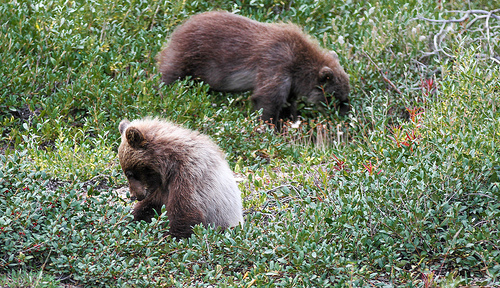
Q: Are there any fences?
A: No, there are no fences.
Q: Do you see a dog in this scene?
A: No, there are no dogs.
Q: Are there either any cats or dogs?
A: No, there are no dogs or cats.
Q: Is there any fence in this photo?
A: No, there are no fences.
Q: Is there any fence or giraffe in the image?
A: No, there are no fences or giraffes.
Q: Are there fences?
A: No, there are no fences.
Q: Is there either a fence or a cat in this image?
A: No, there are no fences or cats.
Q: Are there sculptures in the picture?
A: No, there are no sculptures.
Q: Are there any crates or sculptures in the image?
A: No, there are no sculptures or crates.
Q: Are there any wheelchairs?
A: No, there are no wheelchairs.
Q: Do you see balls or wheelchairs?
A: No, there are no wheelchairs or balls.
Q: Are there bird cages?
A: No, there are no bird cages.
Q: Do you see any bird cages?
A: No, there are no bird cages.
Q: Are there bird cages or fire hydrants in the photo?
A: No, there are no bird cages or fire hydrants.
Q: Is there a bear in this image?
A: Yes, there is a bear.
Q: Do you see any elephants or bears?
A: Yes, there is a bear.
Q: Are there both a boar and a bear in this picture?
A: No, there is a bear but no boars.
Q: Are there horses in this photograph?
A: No, there are no horses.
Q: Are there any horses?
A: No, there are no horses.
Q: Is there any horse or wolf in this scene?
A: No, there are no horses or wolves.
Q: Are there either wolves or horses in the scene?
A: No, there are no horses or wolves.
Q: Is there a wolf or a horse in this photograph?
A: No, there are no horses or wolves.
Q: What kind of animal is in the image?
A: The animal is a bear.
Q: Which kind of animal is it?
A: The animal is a bear.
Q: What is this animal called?
A: This is a bear.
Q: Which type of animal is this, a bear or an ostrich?
A: This is a bear.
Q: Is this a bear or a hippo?
A: This is a bear.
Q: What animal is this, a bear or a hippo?
A: This is a bear.